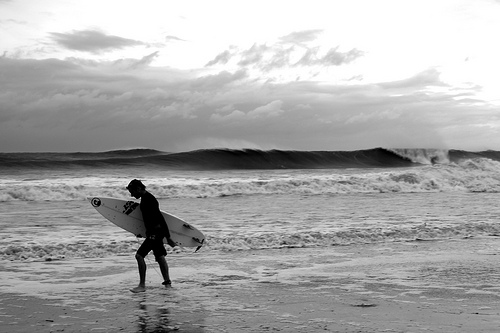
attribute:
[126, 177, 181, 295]
man — walking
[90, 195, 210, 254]
surfboard — white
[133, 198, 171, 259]
wetsuit — black, dark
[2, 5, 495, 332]
picture — black, white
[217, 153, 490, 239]
waves — high, white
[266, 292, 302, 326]
sand — wet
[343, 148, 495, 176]
wave — large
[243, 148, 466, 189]
water — choppy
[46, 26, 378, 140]
clouds — large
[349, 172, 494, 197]
foam — white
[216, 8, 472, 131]
sky — grey, cloudy